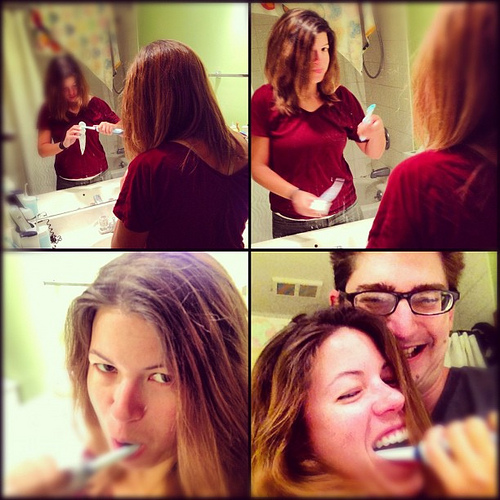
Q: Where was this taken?
A: A bathroom.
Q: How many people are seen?
A: 2.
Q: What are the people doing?
A: Brushing their teeth.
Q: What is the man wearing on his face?
A: Glasses.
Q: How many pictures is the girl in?
A: 4.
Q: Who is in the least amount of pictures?
A: The man.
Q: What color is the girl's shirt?
A: Red.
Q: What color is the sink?
A: White.